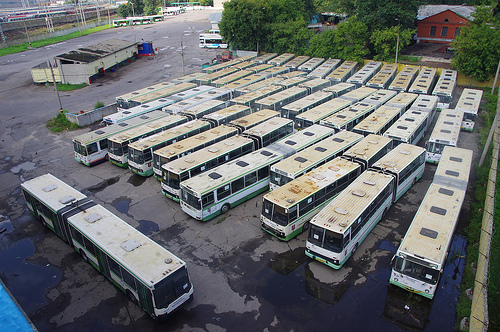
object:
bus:
[72, 88, 232, 167]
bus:
[389, 146, 474, 300]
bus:
[422, 109, 465, 166]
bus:
[194, 61, 256, 87]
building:
[414, 4, 495, 45]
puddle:
[252, 234, 469, 332]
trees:
[216, 0, 417, 65]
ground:
[285, 267, 369, 309]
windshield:
[151, 265, 191, 309]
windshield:
[128, 147, 145, 165]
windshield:
[260, 198, 289, 227]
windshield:
[179, 185, 201, 211]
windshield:
[392, 256, 439, 285]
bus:
[250, 52, 277, 65]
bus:
[292, 86, 376, 133]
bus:
[160, 117, 294, 203]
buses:
[453, 88, 483, 133]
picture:
[185, 42, 465, 282]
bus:
[202, 55, 257, 76]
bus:
[318, 89, 397, 134]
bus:
[304, 143, 426, 270]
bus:
[106, 99, 224, 168]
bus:
[179, 124, 335, 223]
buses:
[346, 61, 383, 89]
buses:
[365, 64, 398, 91]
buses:
[408, 67, 438, 96]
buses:
[282, 56, 311, 73]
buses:
[266, 53, 295, 67]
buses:
[431, 69, 458, 112]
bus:
[102, 85, 217, 129]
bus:
[268, 129, 364, 192]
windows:
[217, 183, 232, 201]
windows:
[307, 223, 343, 253]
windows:
[68, 223, 99, 259]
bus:
[219, 67, 290, 94]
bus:
[228, 77, 309, 109]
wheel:
[221, 205, 230, 214]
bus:
[152, 109, 280, 182]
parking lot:
[9, 35, 485, 329]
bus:
[259, 134, 393, 243]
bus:
[253, 78, 331, 113]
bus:
[383, 94, 440, 154]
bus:
[210, 64, 275, 88]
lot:
[11, 39, 498, 329]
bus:
[17, 173, 194, 319]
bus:
[279, 83, 356, 121]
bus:
[349, 92, 418, 137]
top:
[416, 4, 482, 22]